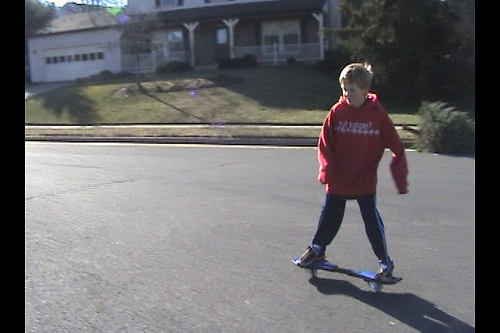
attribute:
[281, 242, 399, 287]
ripstick — in the picture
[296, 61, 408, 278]
boy — in the picture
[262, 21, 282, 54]
window — large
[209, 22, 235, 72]
door — in the picture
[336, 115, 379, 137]
pattern — white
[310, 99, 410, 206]
sweatshirt — red, hooded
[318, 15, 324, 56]
post — large, white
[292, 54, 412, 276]
person — in the picture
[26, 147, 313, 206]
crack — in the picture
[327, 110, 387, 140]
writing — white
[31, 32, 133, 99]
door — white, garage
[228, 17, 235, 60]
white post — in the picture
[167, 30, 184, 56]
window — large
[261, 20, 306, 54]
window — large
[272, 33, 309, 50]
window — large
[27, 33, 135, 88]
garage door — white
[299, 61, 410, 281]
child — small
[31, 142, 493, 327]
asphalt — in the picture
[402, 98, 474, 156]
tree — pine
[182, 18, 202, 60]
post — large, white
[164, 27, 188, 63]
window — large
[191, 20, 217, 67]
door — brown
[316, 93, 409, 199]
shirt — red